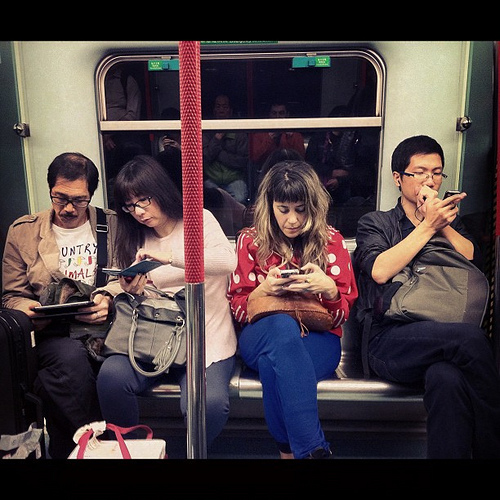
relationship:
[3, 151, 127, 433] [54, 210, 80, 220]
man with mustache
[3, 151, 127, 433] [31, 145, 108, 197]
man has hair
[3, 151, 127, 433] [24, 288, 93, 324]
man looking at a tablet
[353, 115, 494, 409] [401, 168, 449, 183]
asian in eyeglasses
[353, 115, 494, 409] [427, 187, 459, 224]
asian on phone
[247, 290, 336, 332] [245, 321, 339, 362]
bag in lap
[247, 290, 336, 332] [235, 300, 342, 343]
bag in lap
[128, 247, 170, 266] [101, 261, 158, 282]
hand turning pages of a book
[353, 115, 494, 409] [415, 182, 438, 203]
asian holding h hand up to h mouth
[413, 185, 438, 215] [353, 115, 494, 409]
hand of asian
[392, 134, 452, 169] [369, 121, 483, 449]
hair on man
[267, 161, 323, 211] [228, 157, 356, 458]
hair on passengers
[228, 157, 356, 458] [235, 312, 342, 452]
passengers wearing jeans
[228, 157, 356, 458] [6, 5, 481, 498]
passengers sitting on train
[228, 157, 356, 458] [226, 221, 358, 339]
passengers wearing shirt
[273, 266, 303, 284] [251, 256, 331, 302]
phone in hands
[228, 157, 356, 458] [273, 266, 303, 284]
passengers holding phone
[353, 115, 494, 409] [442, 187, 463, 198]
asian holds cellphone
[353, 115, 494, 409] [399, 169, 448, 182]
asian wears glasses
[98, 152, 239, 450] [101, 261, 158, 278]
passengers holds book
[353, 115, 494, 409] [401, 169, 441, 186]
asian on glasses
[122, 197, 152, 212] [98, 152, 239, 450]
eyeglasses on passengers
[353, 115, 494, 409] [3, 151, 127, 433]
asian on man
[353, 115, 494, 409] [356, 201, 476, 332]
asian wearing black jacket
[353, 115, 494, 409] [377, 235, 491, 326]
asian holding bag-lap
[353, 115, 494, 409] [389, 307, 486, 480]
asian wearing pants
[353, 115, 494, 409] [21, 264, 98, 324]
asian holding tablet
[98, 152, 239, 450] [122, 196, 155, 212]
passengers in eyeglasses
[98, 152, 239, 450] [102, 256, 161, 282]
passengers holding book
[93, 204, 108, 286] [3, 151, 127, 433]
strap on bag of man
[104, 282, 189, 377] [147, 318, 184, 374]
handbag with tassels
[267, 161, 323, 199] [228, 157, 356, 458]
hair of passengers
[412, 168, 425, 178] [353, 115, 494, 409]
eye of asian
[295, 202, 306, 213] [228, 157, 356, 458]
eye of passengers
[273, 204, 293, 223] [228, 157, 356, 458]
eye of passengers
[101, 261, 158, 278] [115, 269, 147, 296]
book in hand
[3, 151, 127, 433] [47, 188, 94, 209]
man wearing glasses